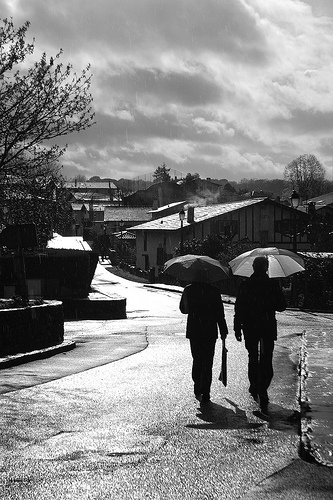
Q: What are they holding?
A: Umbrellas.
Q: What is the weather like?
A: Sunny.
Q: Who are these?
A: People.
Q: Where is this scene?
A: In the rain.